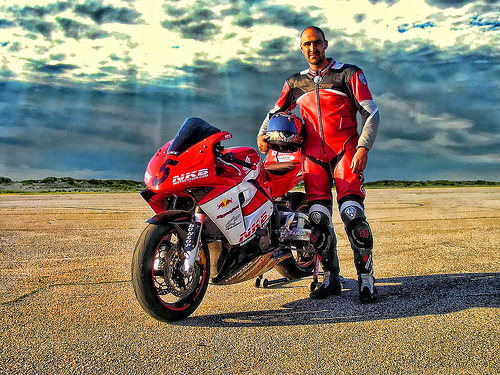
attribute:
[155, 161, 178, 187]
5 — black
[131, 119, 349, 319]
bike — red, white, red,white, black, standing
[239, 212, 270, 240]
nkb — red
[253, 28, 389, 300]
man — middle aged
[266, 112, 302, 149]
helmet — blue, silver, black, closed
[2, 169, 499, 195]
mountains — low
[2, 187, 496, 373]
pavement — concrete, grey, flat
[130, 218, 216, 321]
tire — black, circular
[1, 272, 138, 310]
crack — thin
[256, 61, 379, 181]
motorcycle jacket — red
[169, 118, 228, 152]
windshield — black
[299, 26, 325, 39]
short hair — black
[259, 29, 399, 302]
outfit — red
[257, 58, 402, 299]
safet gear — doed